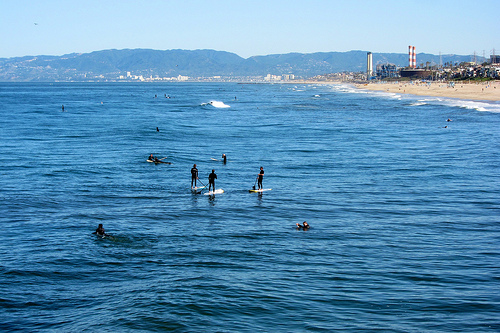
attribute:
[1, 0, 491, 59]
sky — clear, blue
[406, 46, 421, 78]
columns — white, orange, large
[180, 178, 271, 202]
boats — mini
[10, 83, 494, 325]
water — blue